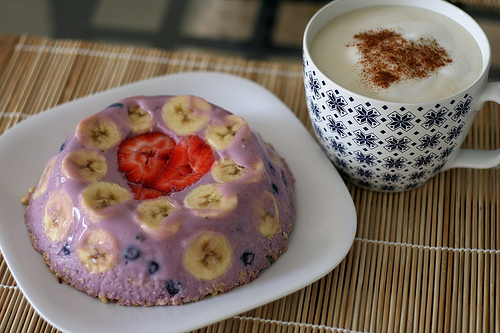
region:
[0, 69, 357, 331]
white square plate with desert on it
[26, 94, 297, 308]
desert sitting on a white square plate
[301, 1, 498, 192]
black and white cup sitting on the table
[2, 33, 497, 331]
brown and white straw placemat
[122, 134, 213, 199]
cherries in the middle of the desert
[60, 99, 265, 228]
sliced bananas on top of the desert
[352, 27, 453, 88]
cinnamon on top of the drink in the cup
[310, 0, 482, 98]
drink in the black and white cup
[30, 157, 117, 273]
sliced bananas on the left side of the desert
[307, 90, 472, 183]
black and white design on the cup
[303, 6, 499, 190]
oat in a cup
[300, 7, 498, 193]
white flowery cup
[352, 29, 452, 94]
cinnamon on a cup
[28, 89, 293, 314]
purple flan with banana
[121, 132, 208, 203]
strawberries in a purple flan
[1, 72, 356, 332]
white plate with purple flan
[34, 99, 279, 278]
sliced bananas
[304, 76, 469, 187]
a bunch of blue flowers in white cup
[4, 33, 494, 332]
bamboo tablecloth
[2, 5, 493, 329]
breakfast served on bamboo table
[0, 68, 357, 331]
a square white plate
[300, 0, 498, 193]
a white coffee cup with a blue design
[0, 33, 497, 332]
a brown wicker placemat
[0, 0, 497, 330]
a plate and cup sitting on a placemat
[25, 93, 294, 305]
a dessert containing strawberries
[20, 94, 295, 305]
a dessert containing bananas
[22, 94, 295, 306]
a dessert containing blueberries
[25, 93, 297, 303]
a dessert containing three types of fruit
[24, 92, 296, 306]
a round purple fruit filled dessert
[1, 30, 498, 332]
a wicker place mat sewn with white thread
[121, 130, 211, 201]
the strawberries in the center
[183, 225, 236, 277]
the banana slice in the cake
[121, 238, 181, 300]
the blueberries in the cake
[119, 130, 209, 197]
the heart in the middle of the cake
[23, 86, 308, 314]
the dessert on the white plate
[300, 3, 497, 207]
the mug on the table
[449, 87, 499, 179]
the white mug handle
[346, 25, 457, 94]
the brown substance on top of the drink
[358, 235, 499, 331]
the placemat underneath the white mug and plate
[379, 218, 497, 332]
the bamboo sticks on the place mat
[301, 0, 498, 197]
a white cup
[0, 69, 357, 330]
A white plate with a pudding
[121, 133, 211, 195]
sliced strawberries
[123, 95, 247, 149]
bananas in a pudding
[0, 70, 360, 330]
a white plate on a lunch mat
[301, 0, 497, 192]
A white cup on a lunch mat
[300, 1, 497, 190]
A white cup with blue drawing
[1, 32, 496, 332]
a light brown lunch mat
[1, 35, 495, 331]
a bamboo lunch mat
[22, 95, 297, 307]
a purple pudding on a white plate